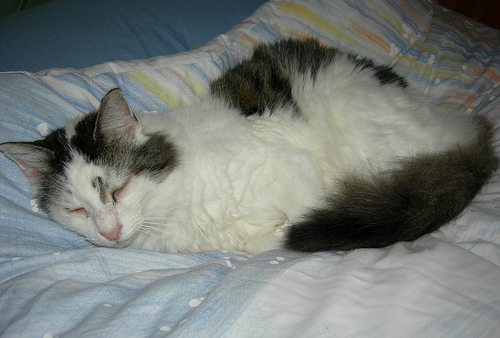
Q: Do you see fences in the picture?
A: No, there are no fences.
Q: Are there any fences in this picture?
A: No, there are no fences.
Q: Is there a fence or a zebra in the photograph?
A: No, there are no fences or zebras.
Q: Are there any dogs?
A: No, there are no dogs.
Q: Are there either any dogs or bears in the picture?
A: No, there are no dogs or bears.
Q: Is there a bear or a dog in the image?
A: No, there are no dogs or bears.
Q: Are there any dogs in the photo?
A: No, there are no dogs.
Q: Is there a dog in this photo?
A: No, there are no dogs.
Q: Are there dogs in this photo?
A: No, there are no dogs.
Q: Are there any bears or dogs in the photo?
A: No, there are no dogs or bears.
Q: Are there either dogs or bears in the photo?
A: No, there are no dogs or bears.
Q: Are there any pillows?
A: Yes, there is a pillow.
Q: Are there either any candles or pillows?
A: Yes, there is a pillow.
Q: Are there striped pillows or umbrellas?
A: Yes, there is a striped pillow.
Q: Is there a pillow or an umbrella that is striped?
A: Yes, the pillow is striped.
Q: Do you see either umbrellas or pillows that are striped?
A: Yes, the pillow is striped.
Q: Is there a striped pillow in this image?
A: Yes, there is a striped pillow.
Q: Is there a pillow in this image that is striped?
A: Yes, there is a pillow that is striped.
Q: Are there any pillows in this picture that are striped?
A: Yes, there is a pillow that is striped.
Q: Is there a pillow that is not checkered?
A: Yes, there is a striped pillow.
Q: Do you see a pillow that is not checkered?
A: Yes, there is a striped pillow.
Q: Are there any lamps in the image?
A: No, there are no lamps.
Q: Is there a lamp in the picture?
A: No, there are no lamps.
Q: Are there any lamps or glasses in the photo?
A: No, there are no lamps or glasses.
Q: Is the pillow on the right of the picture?
A: Yes, the pillow is on the right of the image.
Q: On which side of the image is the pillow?
A: The pillow is on the right of the image.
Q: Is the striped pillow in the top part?
A: Yes, the pillow is in the top of the image.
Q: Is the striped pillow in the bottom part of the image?
A: No, the pillow is in the top of the image.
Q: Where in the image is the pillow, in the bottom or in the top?
A: The pillow is in the top of the image.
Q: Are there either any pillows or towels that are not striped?
A: No, there is a pillow but it is striped.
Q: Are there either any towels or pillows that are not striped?
A: No, there is a pillow but it is striped.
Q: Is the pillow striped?
A: Yes, the pillow is striped.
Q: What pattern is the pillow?
A: The pillow is striped.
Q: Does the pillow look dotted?
A: No, the pillow is striped.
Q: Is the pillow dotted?
A: No, the pillow is striped.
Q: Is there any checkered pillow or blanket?
A: No, there is a pillow but it is striped.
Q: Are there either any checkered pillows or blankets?
A: No, there is a pillow but it is striped.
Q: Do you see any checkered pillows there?
A: No, there is a pillow but it is striped.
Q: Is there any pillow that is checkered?
A: No, there is a pillow but it is striped.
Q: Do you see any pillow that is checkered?
A: No, there is a pillow but it is striped.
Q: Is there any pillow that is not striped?
A: No, there is a pillow but it is striped.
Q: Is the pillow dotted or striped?
A: The pillow is striped.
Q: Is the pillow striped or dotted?
A: The pillow is striped.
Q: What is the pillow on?
A: The pillow is on the bed.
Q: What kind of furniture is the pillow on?
A: The pillow is on the bed.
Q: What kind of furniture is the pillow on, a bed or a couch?
A: The pillow is on a bed.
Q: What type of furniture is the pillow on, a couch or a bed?
A: The pillow is on a bed.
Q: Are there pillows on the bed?
A: Yes, there is a pillow on the bed.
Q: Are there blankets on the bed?
A: No, there is a pillow on the bed.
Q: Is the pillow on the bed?
A: Yes, the pillow is on the bed.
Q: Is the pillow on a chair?
A: No, the pillow is on the bed.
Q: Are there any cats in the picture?
A: Yes, there is a cat.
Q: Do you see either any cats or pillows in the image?
A: Yes, there is a cat.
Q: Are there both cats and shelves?
A: No, there is a cat but no shelves.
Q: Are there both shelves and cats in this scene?
A: No, there is a cat but no shelves.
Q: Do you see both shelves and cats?
A: No, there is a cat but no shelves.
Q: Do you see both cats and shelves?
A: No, there is a cat but no shelves.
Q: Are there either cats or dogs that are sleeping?
A: Yes, the cat is sleeping.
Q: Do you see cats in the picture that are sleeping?
A: Yes, there is a cat that is sleeping.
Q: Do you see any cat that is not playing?
A: Yes, there is a cat that is sleeping .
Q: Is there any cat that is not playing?
A: Yes, there is a cat that is sleeping.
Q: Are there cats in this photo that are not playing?
A: Yes, there is a cat that is sleeping.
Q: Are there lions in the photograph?
A: No, there are no lions.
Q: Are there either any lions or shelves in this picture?
A: No, there are no lions or shelves.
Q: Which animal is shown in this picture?
A: The animal is a cat.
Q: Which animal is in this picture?
A: The animal is a cat.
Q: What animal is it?
A: The animal is a cat.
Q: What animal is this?
A: This is a cat.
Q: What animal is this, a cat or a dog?
A: This is a cat.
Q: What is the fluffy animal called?
A: The animal is a cat.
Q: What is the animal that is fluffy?
A: The animal is a cat.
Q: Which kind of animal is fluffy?
A: The animal is a cat.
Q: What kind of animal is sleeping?
A: The animal is a cat.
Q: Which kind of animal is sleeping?
A: The animal is a cat.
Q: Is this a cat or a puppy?
A: This is a cat.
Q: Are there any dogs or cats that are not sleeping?
A: No, there is a cat but it is sleeping.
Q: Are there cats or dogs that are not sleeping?
A: No, there is a cat but it is sleeping.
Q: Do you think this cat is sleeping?
A: Yes, the cat is sleeping.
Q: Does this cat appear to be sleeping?
A: Yes, the cat is sleeping.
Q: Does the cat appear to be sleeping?
A: Yes, the cat is sleeping.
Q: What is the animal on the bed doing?
A: The cat is sleeping.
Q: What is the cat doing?
A: The cat is sleeping.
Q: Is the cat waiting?
A: No, the cat is sleeping.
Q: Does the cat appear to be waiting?
A: No, the cat is sleeping.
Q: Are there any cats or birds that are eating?
A: No, there is a cat but it is sleeping.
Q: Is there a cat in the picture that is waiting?
A: No, there is a cat but it is sleeping.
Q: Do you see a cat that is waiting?
A: No, there is a cat but it is sleeping.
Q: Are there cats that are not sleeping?
A: No, there is a cat but it is sleeping.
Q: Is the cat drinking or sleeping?
A: The cat is sleeping.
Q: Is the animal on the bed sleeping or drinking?
A: The cat is sleeping.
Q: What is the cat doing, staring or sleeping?
A: The cat is sleeping.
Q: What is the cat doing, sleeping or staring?
A: The cat is sleeping.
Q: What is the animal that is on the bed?
A: The animal is a cat.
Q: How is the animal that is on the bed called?
A: The animal is a cat.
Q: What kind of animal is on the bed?
A: The animal is a cat.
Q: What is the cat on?
A: The cat is on the bed.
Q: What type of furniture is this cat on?
A: The cat is on the bed.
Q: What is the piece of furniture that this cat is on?
A: The piece of furniture is a bed.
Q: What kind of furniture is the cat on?
A: The cat is on the bed.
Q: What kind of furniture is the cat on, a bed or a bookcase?
A: The cat is on a bed.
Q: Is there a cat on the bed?
A: Yes, there is a cat on the bed.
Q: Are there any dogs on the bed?
A: No, there is a cat on the bed.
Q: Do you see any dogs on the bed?
A: No, there is a cat on the bed.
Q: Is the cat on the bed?
A: Yes, the cat is on the bed.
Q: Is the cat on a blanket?
A: No, the cat is on the bed.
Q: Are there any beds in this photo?
A: Yes, there is a bed.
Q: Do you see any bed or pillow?
A: Yes, there is a bed.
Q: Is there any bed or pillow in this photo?
A: Yes, there is a bed.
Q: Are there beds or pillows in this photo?
A: Yes, there is a bed.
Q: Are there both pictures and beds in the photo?
A: No, there is a bed but no pictures.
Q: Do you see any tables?
A: No, there are no tables.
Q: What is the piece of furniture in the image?
A: The piece of furniture is a bed.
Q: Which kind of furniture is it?
A: The piece of furniture is a bed.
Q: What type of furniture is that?
A: That is a bed.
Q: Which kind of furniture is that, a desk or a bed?
A: That is a bed.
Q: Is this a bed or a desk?
A: This is a bed.